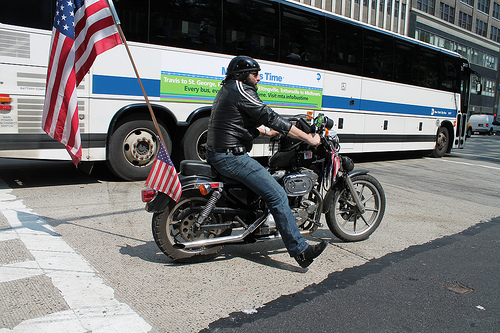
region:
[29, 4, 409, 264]
man on a motorcycle on a street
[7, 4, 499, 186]
blue and white bus on the road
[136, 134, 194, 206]
American flag on a motorcycle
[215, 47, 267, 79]
black helmet of a motorcyclist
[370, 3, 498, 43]
buildings in the background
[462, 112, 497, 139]
white van parked on road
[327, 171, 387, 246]
front wheel of a motorcycle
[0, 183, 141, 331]
white painted lines on the street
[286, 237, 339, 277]
right boot of a motorcyclist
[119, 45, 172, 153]
wooden pole of a flag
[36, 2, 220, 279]
two american flags on motorcycle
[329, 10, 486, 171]
Front of Large city bus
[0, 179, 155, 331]
walkway for crossing the street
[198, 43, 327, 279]
motorcyclist waiting for something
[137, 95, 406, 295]
motorcycle stopped near a bus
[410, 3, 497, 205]
city bus waiting in traffic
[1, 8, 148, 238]
back of city bus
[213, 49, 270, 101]
motorcyclist's helmet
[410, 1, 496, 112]
tall buildings in city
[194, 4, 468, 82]
people riding on bus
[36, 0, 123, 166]
The large American flag on the back of the motorcycle.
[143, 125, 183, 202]
The small American flag on the back of the motorcycle.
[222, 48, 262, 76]
The black helmet the man is wearing.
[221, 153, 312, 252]
The blue jeans the man is wearing.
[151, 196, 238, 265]
The motorcycle's back tire.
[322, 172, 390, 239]
The motorcycle's front tire.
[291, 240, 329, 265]
The man's black boot.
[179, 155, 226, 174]
The black seat on the motorcycle.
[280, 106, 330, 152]
The handle bars of the motorcycle.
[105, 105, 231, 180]
The two rear back tires on the bus.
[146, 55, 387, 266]
A man in a leather jacket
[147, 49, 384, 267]
A man riding a motorcycle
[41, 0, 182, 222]
Two American flags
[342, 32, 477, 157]
A white bus with a blue stripe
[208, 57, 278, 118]
A man wearing a black helmet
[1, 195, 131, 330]
White lines on a street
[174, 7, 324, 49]
Black windows on a bus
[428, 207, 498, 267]
Two colors of pavemen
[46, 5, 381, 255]
Two flags on the back of a motorcycle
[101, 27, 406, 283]
A man on a motorcycle next to a bus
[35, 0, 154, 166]
an American flag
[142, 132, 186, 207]
an American flag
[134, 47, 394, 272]
a man riding on a motorcycle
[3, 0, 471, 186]
a white, black and blue bus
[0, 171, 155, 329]
a painted white crosswalk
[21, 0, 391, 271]
a man riding a motorcycle with American flags attached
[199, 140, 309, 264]
a pair of men's blue jeans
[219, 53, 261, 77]
a black motorcycle helmet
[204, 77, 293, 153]
a black and white jacket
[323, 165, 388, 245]
a motorcycle's front tire